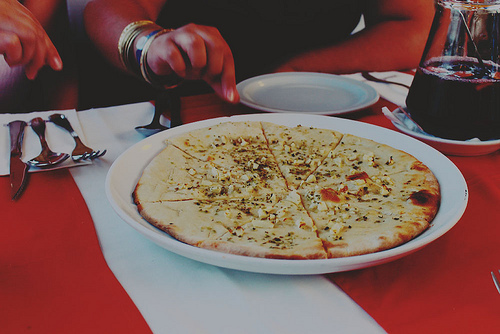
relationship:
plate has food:
[104, 108, 472, 277] [133, 117, 442, 259]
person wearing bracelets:
[81, 0, 456, 104] [116, 18, 176, 92]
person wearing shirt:
[81, 0, 456, 104] [155, 1, 367, 83]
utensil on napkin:
[7, 118, 27, 201] [1, 107, 91, 177]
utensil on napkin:
[26, 116, 69, 177] [1, 107, 91, 177]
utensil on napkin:
[49, 112, 105, 163] [1, 107, 91, 177]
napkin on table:
[1, 107, 91, 177] [0, 68, 499, 333]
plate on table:
[230, 70, 382, 118] [0, 68, 499, 333]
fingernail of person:
[225, 86, 238, 105] [81, 0, 456, 104]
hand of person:
[150, 19, 243, 112] [81, 0, 456, 104]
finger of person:
[218, 33, 240, 108] [81, 0, 456, 104]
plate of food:
[104, 108, 472, 277] [133, 117, 442, 259]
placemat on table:
[0, 168, 151, 332] [0, 68, 499, 333]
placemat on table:
[145, 69, 499, 333] [0, 68, 499, 333]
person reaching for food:
[81, 0, 456, 104] [133, 117, 442, 259]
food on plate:
[133, 117, 442, 259] [104, 108, 472, 277]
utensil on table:
[7, 118, 27, 201] [0, 68, 499, 333]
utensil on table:
[26, 116, 69, 177] [0, 68, 499, 333]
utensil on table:
[49, 112, 105, 163] [0, 68, 499, 333]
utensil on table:
[134, 93, 166, 137] [0, 68, 499, 333]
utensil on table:
[168, 90, 185, 129] [0, 68, 499, 333]